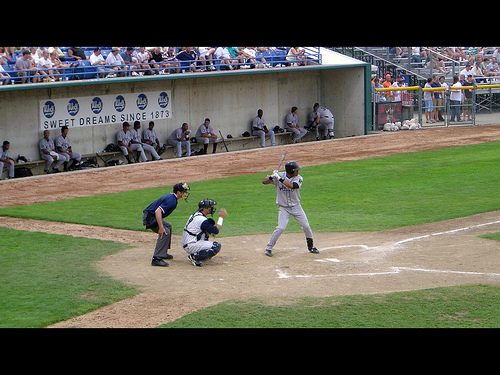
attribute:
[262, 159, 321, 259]
batter — waiting, ready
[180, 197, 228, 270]
catcher — awaiting, preparing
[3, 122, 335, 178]
bench — long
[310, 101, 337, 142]
player — waiting, standing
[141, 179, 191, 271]
umpire — preparing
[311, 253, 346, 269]
plate — home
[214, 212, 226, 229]
band — thick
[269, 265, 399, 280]
line — chalk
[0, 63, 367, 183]
area — dugout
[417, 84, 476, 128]
gate — steel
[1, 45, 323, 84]
area — spectator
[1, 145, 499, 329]
grass — green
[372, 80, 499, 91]
guard — yellow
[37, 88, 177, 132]
banner — white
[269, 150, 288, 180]
bat — baseball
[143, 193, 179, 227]
shirt — blue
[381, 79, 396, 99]
shirt — orange